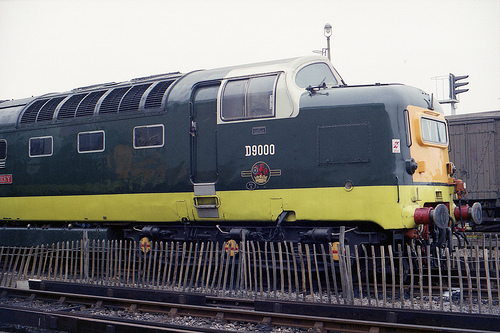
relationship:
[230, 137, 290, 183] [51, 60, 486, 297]
logo on train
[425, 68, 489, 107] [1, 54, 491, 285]
cage above train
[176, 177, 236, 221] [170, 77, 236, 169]
step under door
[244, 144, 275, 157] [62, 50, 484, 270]
number on car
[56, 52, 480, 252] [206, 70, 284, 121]
window on car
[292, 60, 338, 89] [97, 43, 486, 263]
windshield on car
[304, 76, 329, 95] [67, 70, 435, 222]
wiper on car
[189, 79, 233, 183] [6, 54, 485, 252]
door to car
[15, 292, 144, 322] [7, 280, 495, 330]
gravel next to track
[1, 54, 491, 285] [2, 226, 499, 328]
train stopped on track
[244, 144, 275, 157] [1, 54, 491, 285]
number on train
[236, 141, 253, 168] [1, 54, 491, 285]
letter on train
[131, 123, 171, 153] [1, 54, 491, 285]
window on train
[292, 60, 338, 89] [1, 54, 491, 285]
windshield on train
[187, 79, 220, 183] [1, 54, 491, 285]
door on train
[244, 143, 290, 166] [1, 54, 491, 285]
number on side of train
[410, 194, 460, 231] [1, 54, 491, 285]
bumper on train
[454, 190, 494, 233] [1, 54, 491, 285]
bumper on train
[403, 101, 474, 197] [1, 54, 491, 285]
front of train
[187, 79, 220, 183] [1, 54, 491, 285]
door on side of train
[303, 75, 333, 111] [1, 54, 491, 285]
wiper on train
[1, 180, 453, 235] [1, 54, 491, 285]
stripe on train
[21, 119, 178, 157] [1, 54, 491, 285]
windows on train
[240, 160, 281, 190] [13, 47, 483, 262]
logo on train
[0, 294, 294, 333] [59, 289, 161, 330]
gravel under tracks